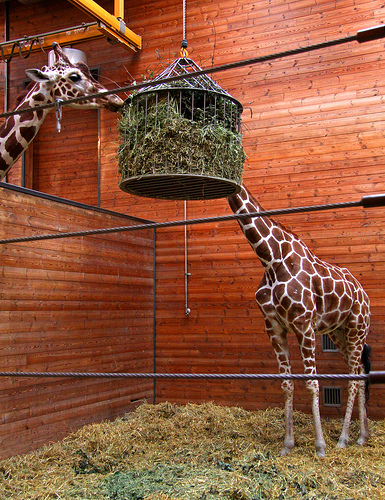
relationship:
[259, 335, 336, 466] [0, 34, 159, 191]
let of giraffe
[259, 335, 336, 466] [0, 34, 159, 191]
leg of giraffe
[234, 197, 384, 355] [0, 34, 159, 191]
body of giraffe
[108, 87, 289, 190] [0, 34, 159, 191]
food for giraffe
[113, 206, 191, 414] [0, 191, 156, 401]
corner of wall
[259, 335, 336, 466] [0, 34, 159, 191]
limb of giraffe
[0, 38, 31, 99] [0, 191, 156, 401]
pipe in wall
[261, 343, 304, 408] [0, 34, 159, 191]
knee of giraffe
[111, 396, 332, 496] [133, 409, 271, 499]
ground in hay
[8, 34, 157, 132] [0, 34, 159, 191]
head of giraffe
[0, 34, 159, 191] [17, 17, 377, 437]
giraffe in pen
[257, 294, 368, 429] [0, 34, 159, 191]
leg of giraffe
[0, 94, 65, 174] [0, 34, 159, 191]
neck of giraffe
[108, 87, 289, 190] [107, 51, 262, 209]
grass in basket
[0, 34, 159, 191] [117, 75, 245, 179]
giraffe eating food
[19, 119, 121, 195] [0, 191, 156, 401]
vents on wall